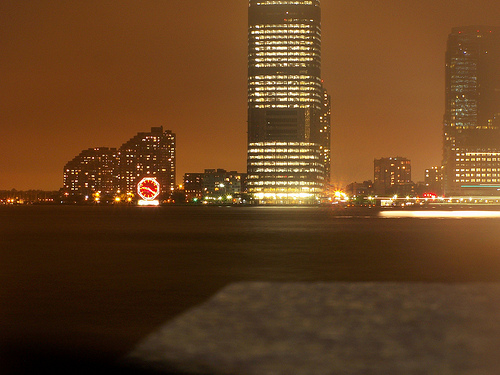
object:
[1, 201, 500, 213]
skyline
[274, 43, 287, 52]
lights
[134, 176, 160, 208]
street light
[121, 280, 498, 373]
asphalt top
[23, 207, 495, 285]
water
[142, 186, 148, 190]
hands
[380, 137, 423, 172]
ground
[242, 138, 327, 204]
bottom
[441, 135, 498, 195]
bottom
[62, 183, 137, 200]
bottom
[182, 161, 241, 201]
building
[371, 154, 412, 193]
building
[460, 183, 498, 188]
light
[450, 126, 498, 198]
building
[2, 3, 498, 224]
city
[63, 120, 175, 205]
building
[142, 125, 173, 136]
roof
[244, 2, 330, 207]
building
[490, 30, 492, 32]
red light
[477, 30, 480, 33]
red light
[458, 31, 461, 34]
red light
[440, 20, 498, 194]
building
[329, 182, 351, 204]
light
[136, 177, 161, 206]
clock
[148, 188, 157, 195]
hands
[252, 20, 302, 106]
office lights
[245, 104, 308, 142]
parking lots